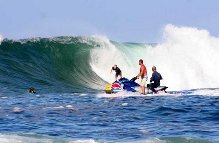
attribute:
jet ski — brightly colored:
[103, 77, 150, 93]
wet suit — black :
[112, 66, 121, 78]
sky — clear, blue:
[16, 1, 175, 33]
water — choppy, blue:
[56, 93, 197, 140]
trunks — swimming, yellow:
[139, 76, 150, 88]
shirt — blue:
[150, 73, 160, 83]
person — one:
[147, 63, 162, 89]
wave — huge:
[18, 32, 106, 90]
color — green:
[103, 42, 149, 55]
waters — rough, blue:
[72, 105, 117, 134]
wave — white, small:
[118, 99, 127, 107]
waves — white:
[163, 23, 209, 84]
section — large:
[168, 25, 214, 84]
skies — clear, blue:
[82, 7, 146, 28]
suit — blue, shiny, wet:
[148, 72, 163, 90]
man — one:
[111, 66, 124, 83]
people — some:
[107, 58, 163, 90]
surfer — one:
[109, 63, 120, 82]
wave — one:
[95, 56, 109, 81]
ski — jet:
[128, 84, 167, 94]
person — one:
[22, 82, 39, 96]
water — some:
[11, 87, 28, 101]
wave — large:
[25, 33, 101, 66]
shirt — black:
[110, 64, 131, 77]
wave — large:
[11, 34, 213, 105]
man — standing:
[135, 58, 157, 93]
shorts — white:
[135, 75, 158, 92]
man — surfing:
[107, 60, 122, 83]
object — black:
[20, 81, 58, 101]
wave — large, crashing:
[22, 31, 212, 97]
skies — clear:
[14, 1, 192, 38]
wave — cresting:
[3, 37, 107, 92]